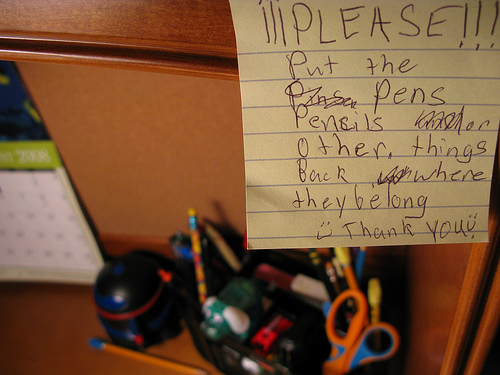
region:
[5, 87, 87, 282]
Calendar on the back board.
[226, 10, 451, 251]
A yellow paper with notes.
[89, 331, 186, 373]
A pencil on the table.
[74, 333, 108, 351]
A blue eraser on the pencil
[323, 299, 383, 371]
A pair of orange and blue scissors.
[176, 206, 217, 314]
A pencil in the pencil holder.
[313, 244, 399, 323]
Pencils in the container.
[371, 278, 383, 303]
The pencil has a yellow eraser.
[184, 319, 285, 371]
The pencil holder is black.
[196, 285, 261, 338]
A piggy bank in the continer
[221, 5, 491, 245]
Note taped to the desk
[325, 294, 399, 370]
Orange and blue scissors on the desk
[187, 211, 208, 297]
Pencil on the desk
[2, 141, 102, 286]
Calander on the desk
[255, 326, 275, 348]
Pencil sharpner on the desk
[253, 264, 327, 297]
Erasers on the desk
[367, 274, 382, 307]
Yellow eraser on a pencil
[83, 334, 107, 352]
Blue eraser on a pencil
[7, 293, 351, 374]
Desk is brown in color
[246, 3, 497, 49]
Please written big on the note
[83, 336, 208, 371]
Pencil on the desk with blue eraser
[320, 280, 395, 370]
Orange and blue scissors, and pencil and yellow eraser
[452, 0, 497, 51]
Three exclamation marks on the righ side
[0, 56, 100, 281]
Blue and green calender on wall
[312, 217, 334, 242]
Smiley face on the left at bottom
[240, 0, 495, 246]
Not regarding the pens and pencils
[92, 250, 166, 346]
Red and blue pencil sharpener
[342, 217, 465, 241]
Thank you at the bottom of note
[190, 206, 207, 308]
Colorful picture with blue end and yellow eraser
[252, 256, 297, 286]
Small pink eraser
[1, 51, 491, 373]
calendar hanging at back of desk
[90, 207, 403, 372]
office supplies on desk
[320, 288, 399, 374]
scissors with orange handles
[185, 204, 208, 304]
upright pencil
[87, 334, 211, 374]
pencil lying down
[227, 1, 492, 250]
handwritten note on lined paper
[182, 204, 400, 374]
black plastic organizer tray with office supplies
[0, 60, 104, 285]
calendar has green rectangle above boxes for each day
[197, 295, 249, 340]
green and white plastic toy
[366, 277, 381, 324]
pencil with yellow eraser cap on top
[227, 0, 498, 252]
Child's note asking that supplies are returned where they belong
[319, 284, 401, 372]
Orange and blue handled scissors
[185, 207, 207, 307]
Multi colored pencil with yellow eraser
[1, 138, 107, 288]
Desk calendar with boxes for note taking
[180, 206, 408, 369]
Pencil caddy filled with pencils scissors and other supplies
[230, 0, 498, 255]
Polite note with several misspellings and scribblings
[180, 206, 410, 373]
Desk supplies in black plastic holder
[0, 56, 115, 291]
2008 pictoral calendar with green border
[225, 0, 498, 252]
Note with large capital letters to start, spelling PLEASE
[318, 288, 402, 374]
Scissors with comfort handles